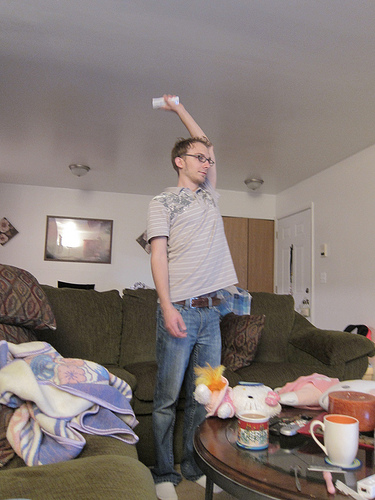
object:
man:
[145, 88, 234, 423]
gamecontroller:
[130, 91, 190, 110]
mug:
[305, 410, 365, 468]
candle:
[314, 470, 342, 499]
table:
[192, 413, 375, 499]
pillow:
[0, 260, 59, 335]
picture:
[42, 207, 115, 266]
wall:
[0, 171, 142, 280]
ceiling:
[10, 0, 360, 139]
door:
[268, 207, 314, 316]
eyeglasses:
[194, 152, 214, 166]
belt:
[182, 295, 225, 309]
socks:
[155, 478, 180, 495]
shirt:
[144, 178, 241, 304]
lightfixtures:
[239, 175, 266, 201]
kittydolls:
[192, 356, 290, 418]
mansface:
[195, 136, 211, 184]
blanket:
[0, 337, 140, 475]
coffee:
[225, 411, 272, 454]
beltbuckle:
[189, 297, 208, 306]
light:
[67, 162, 94, 183]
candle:
[322, 391, 375, 435]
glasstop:
[287, 445, 303, 461]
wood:
[189, 436, 273, 480]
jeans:
[139, 303, 228, 471]